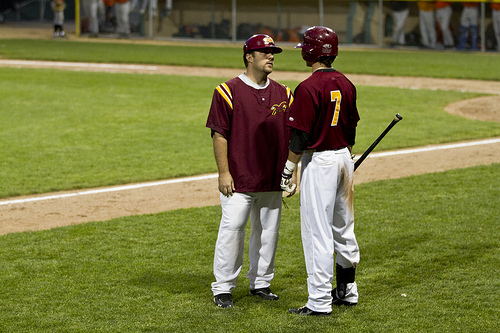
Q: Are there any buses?
A: No, there are no buses.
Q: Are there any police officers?
A: No, there are no police officers.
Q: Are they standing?
A: Yes, the players are standing.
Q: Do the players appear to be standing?
A: Yes, the players are standing.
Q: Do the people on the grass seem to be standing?
A: Yes, the players are standing.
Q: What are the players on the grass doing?
A: The players are standing.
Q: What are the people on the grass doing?
A: The players are standing.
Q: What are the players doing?
A: The players are standing.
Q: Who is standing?
A: The players are standing.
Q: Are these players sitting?
A: No, the players are standing.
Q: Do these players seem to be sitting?
A: No, the players are standing.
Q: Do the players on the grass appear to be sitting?
A: No, the players are standing.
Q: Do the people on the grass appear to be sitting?
A: No, the players are standing.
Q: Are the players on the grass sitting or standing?
A: The players are standing.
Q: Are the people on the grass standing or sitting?
A: The players are standing.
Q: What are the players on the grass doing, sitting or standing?
A: The players are standing.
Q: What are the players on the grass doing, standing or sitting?
A: The players are standing.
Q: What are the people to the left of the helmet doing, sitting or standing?
A: The players are standing.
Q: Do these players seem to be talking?
A: Yes, the players are talking.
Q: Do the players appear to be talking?
A: Yes, the players are talking.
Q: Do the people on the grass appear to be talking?
A: Yes, the players are talking.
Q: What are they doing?
A: The players are talking.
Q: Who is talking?
A: The players are talking.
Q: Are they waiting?
A: No, the players are talking.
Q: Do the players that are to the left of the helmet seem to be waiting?
A: No, the players are talking.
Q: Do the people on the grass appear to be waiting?
A: No, the players are talking.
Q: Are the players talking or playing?
A: The players are talking.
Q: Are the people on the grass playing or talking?
A: The players are talking.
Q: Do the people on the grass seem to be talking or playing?
A: The players are talking.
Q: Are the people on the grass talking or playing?
A: The players are talking.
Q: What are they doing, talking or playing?
A: The players are talking.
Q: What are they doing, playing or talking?
A: The players are talking.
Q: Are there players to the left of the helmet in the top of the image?
A: Yes, there are players to the left of the helmet.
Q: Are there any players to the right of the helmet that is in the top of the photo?
A: No, the players are to the left of the helmet.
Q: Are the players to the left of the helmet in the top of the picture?
A: Yes, the players are to the left of the helmet.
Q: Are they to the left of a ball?
A: No, the players are to the left of the helmet.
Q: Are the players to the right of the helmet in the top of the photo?
A: No, the players are to the left of the helmet.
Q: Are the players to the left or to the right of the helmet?
A: The players are to the left of the helmet.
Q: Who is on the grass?
A: The players are on the grass.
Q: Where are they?
A: The players are on the grass.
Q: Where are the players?
A: The players are on the grass.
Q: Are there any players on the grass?
A: Yes, there are players on the grass.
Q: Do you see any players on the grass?
A: Yes, there are players on the grass.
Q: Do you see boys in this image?
A: No, there are no boys.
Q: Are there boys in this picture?
A: No, there are no boys.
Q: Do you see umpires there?
A: No, there are no umpires.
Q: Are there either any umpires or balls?
A: No, there are no umpires or balls.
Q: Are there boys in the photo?
A: No, there are no boys.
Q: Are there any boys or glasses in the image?
A: No, there are no boys or glasses.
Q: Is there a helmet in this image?
A: Yes, there is a helmet.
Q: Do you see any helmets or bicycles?
A: Yes, there is a helmet.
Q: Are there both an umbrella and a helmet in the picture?
A: No, there is a helmet but no umbrellas.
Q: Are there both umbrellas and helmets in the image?
A: No, there is a helmet but no umbrellas.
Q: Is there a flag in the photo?
A: No, there are no flags.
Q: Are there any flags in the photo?
A: No, there are no flags.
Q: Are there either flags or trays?
A: No, there are no flags or trays.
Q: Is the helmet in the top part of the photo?
A: Yes, the helmet is in the top of the image.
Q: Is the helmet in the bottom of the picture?
A: No, the helmet is in the top of the image.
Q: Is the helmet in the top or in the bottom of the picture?
A: The helmet is in the top of the image.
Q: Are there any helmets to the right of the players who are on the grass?
A: Yes, there is a helmet to the right of the players.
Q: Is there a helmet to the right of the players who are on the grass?
A: Yes, there is a helmet to the right of the players.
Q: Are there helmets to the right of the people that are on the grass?
A: Yes, there is a helmet to the right of the players.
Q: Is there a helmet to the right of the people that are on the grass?
A: Yes, there is a helmet to the right of the players.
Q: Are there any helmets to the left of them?
A: No, the helmet is to the right of the players.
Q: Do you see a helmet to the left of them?
A: No, the helmet is to the right of the players.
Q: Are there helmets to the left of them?
A: No, the helmet is to the right of the players.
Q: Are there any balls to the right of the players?
A: No, there is a helmet to the right of the players.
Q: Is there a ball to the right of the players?
A: No, there is a helmet to the right of the players.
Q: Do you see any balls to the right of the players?
A: No, there is a helmet to the right of the players.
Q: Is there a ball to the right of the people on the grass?
A: No, there is a helmet to the right of the players.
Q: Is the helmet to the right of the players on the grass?
A: Yes, the helmet is to the right of the players.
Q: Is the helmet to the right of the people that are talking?
A: Yes, the helmet is to the right of the players.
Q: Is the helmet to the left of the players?
A: No, the helmet is to the right of the players.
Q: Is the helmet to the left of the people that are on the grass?
A: No, the helmet is to the right of the players.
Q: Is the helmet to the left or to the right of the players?
A: The helmet is to the right of the players.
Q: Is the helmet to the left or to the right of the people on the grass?
A: The helmet is to the right of the players.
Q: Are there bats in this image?
A: Yes, there is a bat.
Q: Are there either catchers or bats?
A: Yes, there is a bat.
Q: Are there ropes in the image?
A: No, there are no ropes.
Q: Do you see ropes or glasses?
A: No, there are no ropes or glasses.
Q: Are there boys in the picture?
A: No, there are no boys.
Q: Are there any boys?
A: No, there are no boys.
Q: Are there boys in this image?
A: No, there are no boys.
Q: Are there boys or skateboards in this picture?
A: No, there are no boys or skateboards.